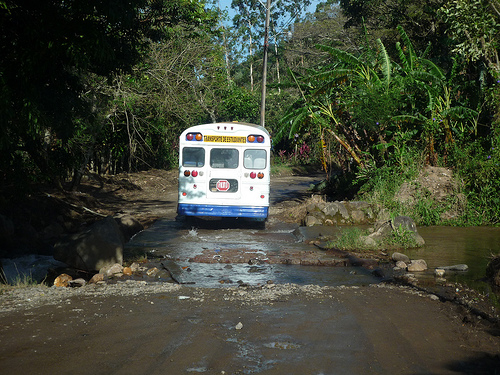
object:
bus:
[180, 123, 272, 228]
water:
[243, 184, 499, 308]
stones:
[407, 260, 427, 272]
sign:
[216, 180, 230, 191]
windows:
[183, 147, 205, 168]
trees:
[1, 1, 155, 225]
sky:
[198, 2, 343, 68]